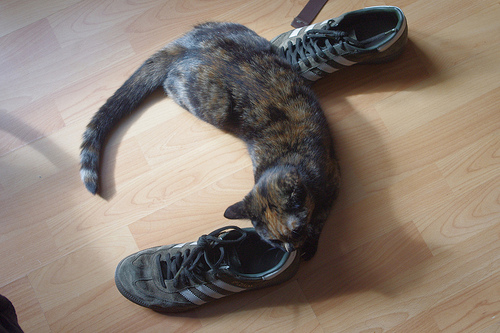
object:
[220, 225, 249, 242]
shoe string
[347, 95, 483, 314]
floor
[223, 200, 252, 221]
ear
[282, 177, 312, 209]
ear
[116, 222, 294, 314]
sneaker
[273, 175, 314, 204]
left ear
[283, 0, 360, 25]
strap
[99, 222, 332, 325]
sneaker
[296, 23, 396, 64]
shoe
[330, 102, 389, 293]
shadow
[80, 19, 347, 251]
cat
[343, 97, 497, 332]
floor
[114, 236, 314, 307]
shoe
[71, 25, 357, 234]
cat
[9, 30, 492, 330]
floor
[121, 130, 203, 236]
shades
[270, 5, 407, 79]
shoe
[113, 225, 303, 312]
shoe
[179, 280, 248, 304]
stripes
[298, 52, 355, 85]
stripes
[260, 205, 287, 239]
gold patch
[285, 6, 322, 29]
strap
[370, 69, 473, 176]
floor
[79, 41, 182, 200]
tail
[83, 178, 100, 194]
stripe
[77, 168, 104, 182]
stripe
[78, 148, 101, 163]
stripe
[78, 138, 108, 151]
stripe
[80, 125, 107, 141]
stripe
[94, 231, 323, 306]
shoe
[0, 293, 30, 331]
black object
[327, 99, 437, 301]
shadows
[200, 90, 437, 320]
shadow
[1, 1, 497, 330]
floor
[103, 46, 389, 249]
cat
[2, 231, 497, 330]
floor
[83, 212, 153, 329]
wood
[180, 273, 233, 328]
stripes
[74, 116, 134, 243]
tail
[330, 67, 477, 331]
floor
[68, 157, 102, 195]
end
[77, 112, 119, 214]
tail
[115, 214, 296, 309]
top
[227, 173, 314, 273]
head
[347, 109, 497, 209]
floor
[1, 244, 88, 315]
pattern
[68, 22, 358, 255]
cat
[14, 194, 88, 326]
different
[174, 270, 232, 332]
strpes